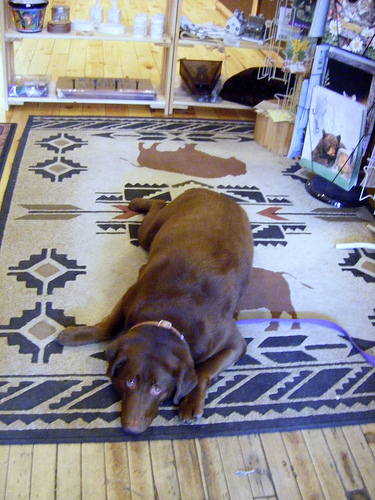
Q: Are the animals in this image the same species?
A: No, they are dogs and bears.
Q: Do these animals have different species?
A: Yes, they are dogs and bears.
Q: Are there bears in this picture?
A: Yes, there is a bear.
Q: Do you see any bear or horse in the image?
A: Yes, there is a bear.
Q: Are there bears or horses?
A: Yes, there is a bear.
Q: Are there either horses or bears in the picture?
A: Yes, there is a bear.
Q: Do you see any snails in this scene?
A: No, there are no snails.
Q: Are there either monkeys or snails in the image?
A: No, there are no snails or monkeys.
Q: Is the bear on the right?
A: Yes, the bear is on the right of the image.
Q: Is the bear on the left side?
A: No, the bear is on the right of the image.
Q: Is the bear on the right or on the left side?
A: The bear is on the right of the image.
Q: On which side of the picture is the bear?
A: The bear is on the right of the image.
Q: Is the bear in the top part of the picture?
A: Yes, the bear is in the top of the image.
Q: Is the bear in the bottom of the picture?
A: No, the bear is in the top of the image.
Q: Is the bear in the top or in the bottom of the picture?
A: The bear is in the top of the image.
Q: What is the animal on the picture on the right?
A: The animal is a bear.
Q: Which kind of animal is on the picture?
A: The animal is a bear.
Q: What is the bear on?
A: The bear is on the picture.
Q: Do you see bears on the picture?
A: Yes, there is a bear on the picture.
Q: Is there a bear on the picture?
A: Yes, there is a bear on the picture.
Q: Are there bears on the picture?
A: Yes, there is a bear on the picture.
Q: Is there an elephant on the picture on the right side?
A: No, there is a bear on the picture.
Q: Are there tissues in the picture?
A: No, there are no tissues.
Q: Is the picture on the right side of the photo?
A: Yes, the picture is on the right of the image.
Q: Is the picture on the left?
A: No, the picture is on the right of the image.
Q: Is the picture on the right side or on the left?
A: The picture is on the right of the image.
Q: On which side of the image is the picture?
A: The picture is on the right of the image.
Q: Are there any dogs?
A: Yes, there is a dog.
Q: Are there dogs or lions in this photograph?
A: Yes, there is a dog.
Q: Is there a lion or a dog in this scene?
A: Yes, there is a dog.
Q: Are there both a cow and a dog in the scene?
A: No, there is a dog but no cows.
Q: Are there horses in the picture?
A: No, there are no horses.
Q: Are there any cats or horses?
A: No, there are no horses or cats.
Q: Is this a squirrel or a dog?
A: This is a dog.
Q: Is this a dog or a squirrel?
A: This is a dog.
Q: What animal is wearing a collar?
A: The dog is wearing a collar.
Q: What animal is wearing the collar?
A: The dog is wearing a collar.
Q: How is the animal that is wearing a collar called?
A: The animal is a dog.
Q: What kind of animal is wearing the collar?
A: The animal is a dog.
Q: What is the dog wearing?
A: The dog is wearing a collar.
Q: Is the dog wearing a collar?
A: Yes, the dog is wearing a collar.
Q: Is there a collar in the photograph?
A: Yes, there is a collar.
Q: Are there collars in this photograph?
A: Yes, there is a collar.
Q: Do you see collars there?
A: Yes, there is a collar.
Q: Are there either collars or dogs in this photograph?
A: Yes, there is a collar.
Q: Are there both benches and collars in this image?
A: No, there is a collar but no benches.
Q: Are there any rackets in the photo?
A: No, there are no rackets.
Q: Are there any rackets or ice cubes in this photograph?
A: No, there are no rackets or ice cubes.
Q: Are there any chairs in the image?
A: No, there are no chairs.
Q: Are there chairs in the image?
A: No, there are no chairs.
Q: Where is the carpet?
A: The carpet is on the floor.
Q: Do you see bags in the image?
A: No, there are no bags.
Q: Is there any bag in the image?
A: No, there are no bags.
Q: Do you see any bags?
A: No, there are no bags.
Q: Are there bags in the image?
A: No, there are no bags.